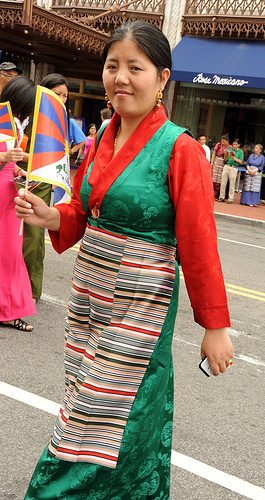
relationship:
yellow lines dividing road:
[223, 280, 264, 303] [211, 212, 264, 289]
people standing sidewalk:
[240, 142, 263, 206] [211, 191, 264, 221]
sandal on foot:
[0, 317, 38, 335] [0, 308, 41, 336]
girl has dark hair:
[14, 36, 237, 497] [97, 17, 171, 78]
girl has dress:
[14, 17, 234, 498] [55, 115, 220, 499]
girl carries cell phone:
[14, 36, 237, 497] [199, 356, 213, 377]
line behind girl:
[225, 277, 263, 306] [14, 17, 234, 498]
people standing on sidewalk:
[240, 142, 264, 206] [212, 199, 263, 220]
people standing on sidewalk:
[217, 139, 244, 205] [212, 199, 263, 220]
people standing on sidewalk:
[210, 133, 231, 200] [212, 199, 263, 220]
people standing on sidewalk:
[196, 135, 209, 166] [212, 199, 263, 220]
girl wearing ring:
[14, 17, 234, 498] [224, 356, 234, 367]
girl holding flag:
[14, 17, 234, 498] [17, 83, 74, 238]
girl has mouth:
[14, 17, 234, 498] [115, 87, 133, 96]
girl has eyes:
[14, 17, 234, 498] [105, 62, 141, 71]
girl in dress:
[14, 17, 234, 498] [22, 103, 231, 498]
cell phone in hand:
[199, 356, 213, 377] [198, 326, 233, 375]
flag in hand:
[12, 59, 87, 227] [14, 186, 53, 230]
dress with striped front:
[22, 103, 231, 498] [75, 128, 184, 205]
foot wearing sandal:
[2, 316, 31, 328] [0, 318, 34, 330]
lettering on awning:
[191, 71, 248, 88] [168, 33, 263, 90]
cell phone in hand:
[195, 356, 216, 378] [198, 326, 233, 375]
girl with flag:
[14, 17, 234, 498] [27, 82, 74, 213]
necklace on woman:
[110, 134, 119, 151] [61, 17, 216, 192]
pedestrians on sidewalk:
[193, 133, 264, 207] [229, 200, 250, 222]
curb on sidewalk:
[213, 211, 262, 229] [211, 182, 263, 229]